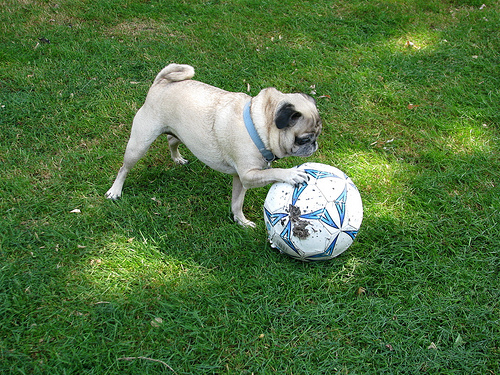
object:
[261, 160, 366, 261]
ball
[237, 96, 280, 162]
collar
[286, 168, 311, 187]
foot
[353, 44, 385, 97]
grass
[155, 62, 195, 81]
tail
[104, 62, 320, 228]
dog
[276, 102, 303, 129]
ear